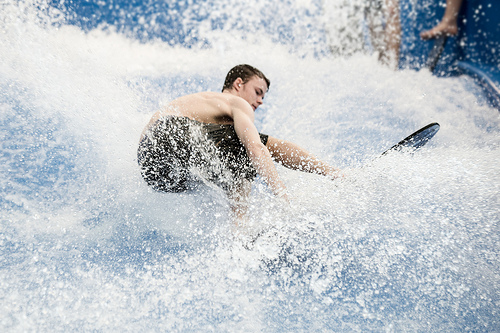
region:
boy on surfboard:
[119, 46, 412, 249]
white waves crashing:
[304, 166, 441, 307]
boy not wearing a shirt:
[157, 46, 324, 186]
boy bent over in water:
[128, 73, 343, 257]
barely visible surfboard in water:
[370, 102, 460, 178]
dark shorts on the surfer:
[123, 113, 250, 203]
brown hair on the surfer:
[221, 61, 279, 99]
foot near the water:
[411, 4, 485, 53]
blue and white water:
[7, 111, 96, 250]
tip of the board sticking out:
[383, 116, 455, 181]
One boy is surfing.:
[146, 66, 438, 268]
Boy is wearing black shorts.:
[123, 114, 323, 211]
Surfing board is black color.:
[320, 108, 455, 205]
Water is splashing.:
[57, 182, 497, 321]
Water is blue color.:
[13, 129, 90, 226]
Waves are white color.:
[44, 34, 448, 299]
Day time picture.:
[34, 16, 489, 313]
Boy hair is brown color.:
[223, 60, 251, 88]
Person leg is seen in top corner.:
[348, 7, 480, 87]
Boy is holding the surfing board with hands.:
[156, 63, 421, 233]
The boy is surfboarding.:
[127, 75, 428, 201]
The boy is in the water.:
[143, 71, 335, 221]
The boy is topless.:
[173, 84, 251, 138]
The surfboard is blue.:
[381, 116, 464, 158]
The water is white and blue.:
[37, 158, 224, 328]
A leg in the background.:
[413, 8, 464, 50]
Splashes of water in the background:
[164, 15, 385, 71]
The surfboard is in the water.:
[311, 109, 436, 162]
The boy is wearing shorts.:
[136, 108, 218, 189]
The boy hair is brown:
[222, 57, 291, 85]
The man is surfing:
[130, 65, 471, 231]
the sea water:
[101, 215, 417, 310]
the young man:
[135, 53, 286, 196]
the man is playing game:
[111, 66, 383, 213]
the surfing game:
[126, 56, 431, 261]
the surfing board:
[341, 123, 442, 194]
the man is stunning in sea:
[120, 51, 440, 227]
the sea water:
[43, 35, 146, 301]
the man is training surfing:
[122, 55, 492, 260]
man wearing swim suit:
[124, 44, 356, 213]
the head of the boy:
[219, 60, 272, 117]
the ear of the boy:
[230, 71, 245, 96]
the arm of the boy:
[229, 96, 304, 202]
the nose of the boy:
[254, 88, 267, 108]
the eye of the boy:
[251, 85, 264, 98]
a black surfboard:
[356, 116, 445, 179]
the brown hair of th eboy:
[219, 56, 276, 91]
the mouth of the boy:
[249, 99, 260, 112]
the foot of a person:
[414, 19, 467, 48]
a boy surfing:
[129, 60, 454, 242]